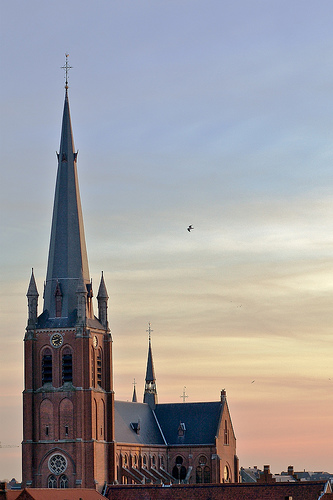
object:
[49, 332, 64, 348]
clock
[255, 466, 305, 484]
chimneys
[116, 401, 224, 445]
roof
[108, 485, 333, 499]
roof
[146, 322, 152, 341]
cross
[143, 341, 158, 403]
steeple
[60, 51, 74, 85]
cross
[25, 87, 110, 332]
roof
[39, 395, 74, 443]
windows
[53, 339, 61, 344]
clock hands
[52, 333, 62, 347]
clock face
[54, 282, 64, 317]
design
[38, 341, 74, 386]
windows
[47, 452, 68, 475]
large window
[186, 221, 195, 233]
bird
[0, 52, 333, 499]
building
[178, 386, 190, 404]
cross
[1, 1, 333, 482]
clouds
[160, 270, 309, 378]
sunset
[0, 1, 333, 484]
sky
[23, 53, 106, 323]
steeple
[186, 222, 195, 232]
bird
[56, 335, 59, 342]
hand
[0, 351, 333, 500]
bands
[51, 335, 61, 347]
number